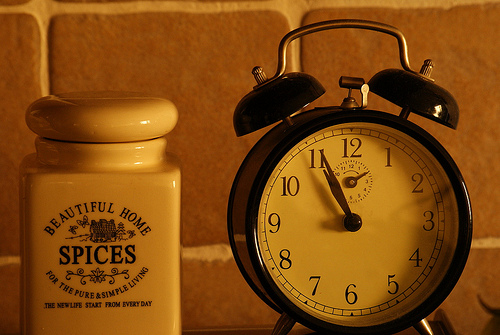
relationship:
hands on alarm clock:
[318, 147, 369, 232] [228, 19, 474, 334]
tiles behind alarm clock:
[0, 1, 500, 334] [228, 19, 474, 334]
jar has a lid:
[18, 136, 182, 334] [25, 91, 179, 143]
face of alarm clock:
[257, 121, 460, 327] [228, 19, 474, 334]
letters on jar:
[42, 200, 153, 309] [18, 136, 182, 334]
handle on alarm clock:
[253, 19, 435, 91] [228, 19, 474, 334]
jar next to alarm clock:
[18, 136, 182, 334] [228, 19, 474, 334]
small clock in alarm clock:
[331, 159, 374, 203] [228, 19, 474, 334]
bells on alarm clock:
[234, 67, 461, 137] [228, 19, 474, 334]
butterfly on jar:
[76, 215, 90, 229] [18, 136, 182, 334]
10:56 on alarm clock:
[257, 120, 461, 325] [228, 19, 474, 334]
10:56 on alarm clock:
[257, 120, 447, 316] [228, 19, 474, 334]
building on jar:
[88, 218, 118, 241] [18, 136, 182, 334]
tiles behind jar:
[0, 1, 500, 334] [18, 136, 182, 334]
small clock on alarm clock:
[331, 159, 374, 203] [228, 19, 474, 334]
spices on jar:
[60, 244, 137, 264] [18, 136, 182, 334]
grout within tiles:
[0, 0, 499, 265] [0, 1, 500, 334]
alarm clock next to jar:
[228, 19, 474, 334] [18, 136, 182, 334]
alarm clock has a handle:
[228, 19, 474, 334] [253, 19, 435, 91]